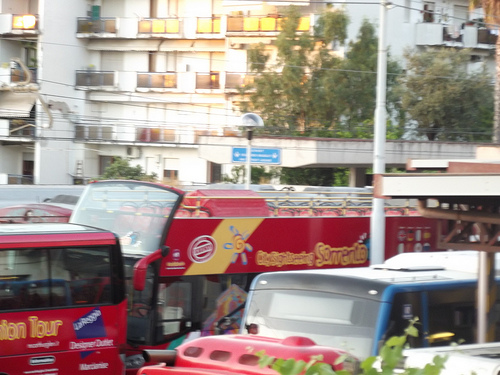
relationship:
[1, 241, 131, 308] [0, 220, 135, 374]
window on bus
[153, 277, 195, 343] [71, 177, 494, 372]
window on bus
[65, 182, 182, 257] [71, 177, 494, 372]
window on bus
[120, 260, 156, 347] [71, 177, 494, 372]
window on bus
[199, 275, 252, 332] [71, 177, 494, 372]
window on bus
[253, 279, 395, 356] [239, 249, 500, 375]
window on bus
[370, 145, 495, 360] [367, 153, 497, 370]
bus stop in area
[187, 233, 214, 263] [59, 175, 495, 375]
logo on bus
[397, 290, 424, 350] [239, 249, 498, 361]
window in front bus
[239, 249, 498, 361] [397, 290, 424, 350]
bus front has window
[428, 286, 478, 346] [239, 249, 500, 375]
window with bus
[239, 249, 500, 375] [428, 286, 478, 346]
bus has window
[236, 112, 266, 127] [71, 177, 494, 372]
light near bus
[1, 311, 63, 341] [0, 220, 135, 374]
words on a bus